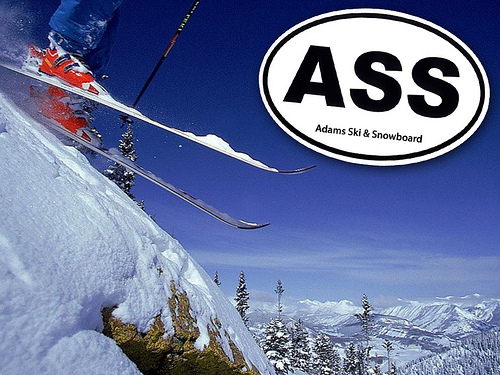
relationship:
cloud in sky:
[285, 241, 467, 297] [190, 153, 474, 311]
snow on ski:
[201, 128, 260, 158] [114, 98, 317, 177]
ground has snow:
[70, 285, 467, 374] [40, 232, 193, 289]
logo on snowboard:
[283, 44, 461, 144] [374, 133, 432, 149]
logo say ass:
[283, 44, 461, 144] [304, 59, 440, 106]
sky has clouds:
[190, 153, 474, 311] [263, 258, 399, 283]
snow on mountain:
[201, 128, 260, 158] [4, 146, 221, 331]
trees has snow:
[238, 282, 365, 375] [273, 335, 287, 359]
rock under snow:
[130, 286, 238, 375] [40, 232, 193, 289]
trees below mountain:
[238, 282, 365, 375] [4, 146, 221, 331]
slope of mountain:
[19, 128, 210, 346] [4, 146, 221, 331]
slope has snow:
[19, 128, 210, 346] [40, 232, 193, 289]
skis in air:
[79, 116, 287, 228] [134, 53, 246, 204]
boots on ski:
[37, 50, 105, 113] [114, 98, 317, 177]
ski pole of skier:
[145, 29, 189, 74] [35, 5, 119, 147]